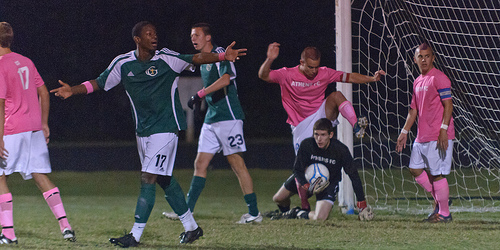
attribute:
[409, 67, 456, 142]
shirt — pink , white 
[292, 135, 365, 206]
shirt — black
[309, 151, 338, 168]
letters — white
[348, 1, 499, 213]
net — white 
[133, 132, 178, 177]
shorts — green, white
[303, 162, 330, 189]
ball — blue , white 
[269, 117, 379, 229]
person — kneeling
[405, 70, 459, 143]
shirt — pink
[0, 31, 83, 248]
man socks — pink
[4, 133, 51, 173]
shorts — white 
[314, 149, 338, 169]
shirt — black 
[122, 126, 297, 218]
shorts — green, white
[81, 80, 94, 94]
armband — pink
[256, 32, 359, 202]
man — wearing